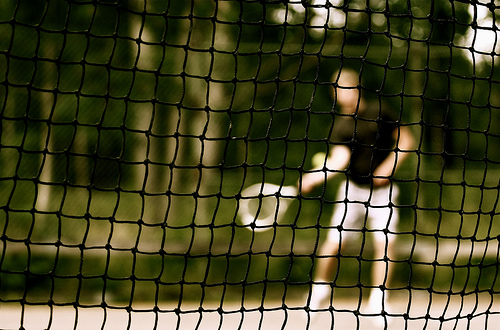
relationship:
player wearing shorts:
[296, 68, 414, 312] [327, 178, 399, 244]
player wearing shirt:
[296, 68, 414, 312] [326, 99, 404, 190]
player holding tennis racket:
[296, 68, 414, 312] [236, 181, 299, 232]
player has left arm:
[296, 68, 414, 312] [371, 101, 415, 182]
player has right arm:
[296, 68, 414, 312] [298, 99, 352, 196]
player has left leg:
[296, 68, 414, 312] [364, 188, 399, 317]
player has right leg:
[296, 68, 414, 312] [306, 178, 365, 311]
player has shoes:
[296, 68, 414, 312] [305, 276, 387, 320]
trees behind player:
[0, 0, 500, 301] [296, 68, 414, 312]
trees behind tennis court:
[0, 0, 500, 301] [0, 297, 500, 329]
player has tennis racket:
[296, 68, 414, 312] [236, 181, 299, 232]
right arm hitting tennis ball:
[298, 99, 352, 196] [313, 151, 326, 168]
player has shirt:
[296, 68, 414, 312] [326, 99, 404, 190]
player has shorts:
[296, 68, 414, 312] [327, 178, 399, 244]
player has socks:
[296, 68, 414, 312] [312, 277, 387, 294]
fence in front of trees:
[0, 28, 499, 301] [0, 0, 500, 301]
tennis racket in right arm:
[236, 181, 299, 232] [298, 99, 352, 196]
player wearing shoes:
[296, 68, 414, 312] [305, 276, 387, 320]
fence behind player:
[0, 28, 499, 301] [296, 68, 414, 312]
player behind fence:
[296, 68, 414, 312] [0, 28, 499, 301]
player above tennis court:
[296, 68, 414, 312] [0, 297, 500, 329]